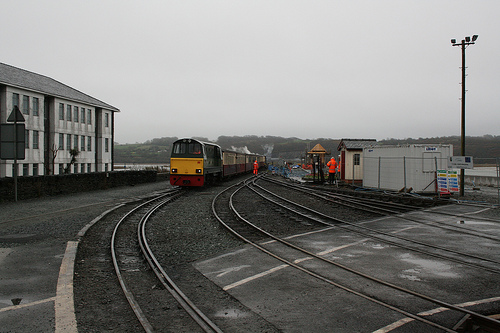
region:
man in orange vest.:
[324, 155, 338, 183]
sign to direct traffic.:
[11, 107, 28, 178]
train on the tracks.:
[165, 145, 250, 179]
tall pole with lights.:
[439, 27, 477, 134]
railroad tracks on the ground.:
[225, 177, 275, 231]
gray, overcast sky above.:
[185, 28, 367, 71]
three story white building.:
[33, 90, 115, 160]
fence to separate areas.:
[356, 159, 423, 181]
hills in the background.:
[118, 140, 163, 157]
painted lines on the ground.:
[55, 235, 72, 330]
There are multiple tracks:
[17, 62, 462, 325]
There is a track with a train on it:
[130, 96, 445, 313]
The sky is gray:
[14, 50, 480, 316]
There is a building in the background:
[0, 55, 441, 317]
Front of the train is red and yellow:
[50, 89, 419, 294]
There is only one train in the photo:
[90, 94, 425, 304]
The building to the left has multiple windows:
[10, 69, 262, 291]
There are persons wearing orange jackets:
[201, 22, 481, 264]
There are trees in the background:
[86, 118, 442, 266]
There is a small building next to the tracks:
[320, 119, 406, 222]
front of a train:
[169, 137, 204, 185]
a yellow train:
[167, 135, 203, 188]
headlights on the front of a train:
[167, 163, 209, 176]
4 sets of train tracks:
[114, 206, 498, 331]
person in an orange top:
[319, 147, 344, 188]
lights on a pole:
[445, 26, 484, 204]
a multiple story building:
[0, 55, 119, 179]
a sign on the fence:
[441, 152, 476, 174]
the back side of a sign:
[0, 105, 27, 165]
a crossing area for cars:
[6, 181, 491, 331]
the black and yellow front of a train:
[166, 132, 202, 187]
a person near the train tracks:
[320, 151, 335, 181]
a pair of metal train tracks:
[101, 181, 221, 326]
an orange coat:
[322, 155, 334, 170]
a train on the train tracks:
[162, 130, 267, 185]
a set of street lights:
[450, 30, 477, 41]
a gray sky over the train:
[0, 0, 498, 140]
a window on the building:
[31, 94, 39, 117]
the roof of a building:
[0, 60, 121, 112]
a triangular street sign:
[6, 103, 26, 122]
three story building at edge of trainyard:
[0, 62, 117, 179]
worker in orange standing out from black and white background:
[318, 152, 339, 180]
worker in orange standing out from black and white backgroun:
[253, 161, 260, 176]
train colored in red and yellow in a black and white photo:
[166, 136, 267, 185]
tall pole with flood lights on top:
[446, 29, 478, 189]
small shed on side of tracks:
[334, 137, 379, 184]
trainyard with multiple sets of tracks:
[0, 190, 499, 331]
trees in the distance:
[111, 136, 498, 171]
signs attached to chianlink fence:
[428, 168, 465, 198]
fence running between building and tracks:
[0, 167, 171, 207]